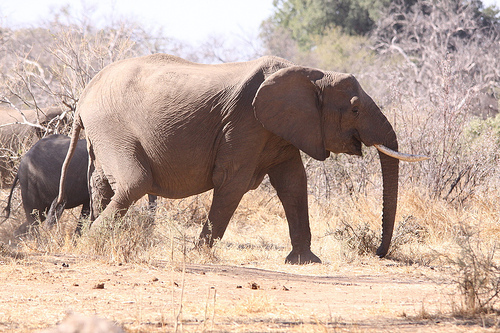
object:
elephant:
[40, 52, 431, 267]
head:
[251, 65, 407, 160]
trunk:
[375, 141, 400, 258]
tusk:
[373, 139, 400, 263]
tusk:
[367, 135, 430, 162]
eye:
[347, 106, 367, 114]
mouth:
[340, 127, 373, 157]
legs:
[80, 145, 338, 269]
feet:
[74, 209, 321, 261]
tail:
[41, 114, 95, 226]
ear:
[250, 64, 330, 162]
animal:
[0, 135, 166, 247]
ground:
[1, 206, 499, 332]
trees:
[1, 0, 499, 195]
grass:
[0, 184, 499, 267]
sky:
[0, 0, 275, 58]